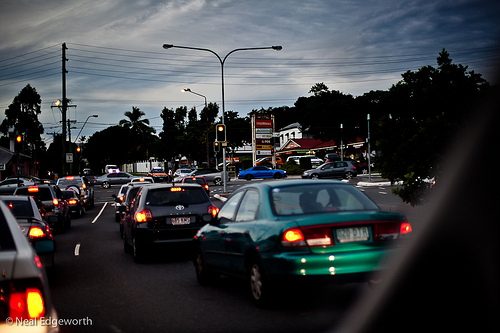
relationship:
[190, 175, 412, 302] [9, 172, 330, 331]
car on street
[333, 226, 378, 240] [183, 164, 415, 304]
license plate on rear car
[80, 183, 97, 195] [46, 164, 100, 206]
tail light on car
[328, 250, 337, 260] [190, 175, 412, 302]
light reflecting on car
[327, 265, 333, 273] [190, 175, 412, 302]
light reflecting on car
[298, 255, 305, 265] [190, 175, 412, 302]
light reflecting on car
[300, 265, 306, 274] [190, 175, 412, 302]
light reflecting on car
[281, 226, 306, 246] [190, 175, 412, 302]
lights on car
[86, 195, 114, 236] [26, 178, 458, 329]
white line on middle of street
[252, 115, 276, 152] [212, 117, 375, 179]
signs for shopping center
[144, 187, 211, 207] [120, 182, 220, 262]
window of a car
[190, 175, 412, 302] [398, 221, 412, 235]
car moving lights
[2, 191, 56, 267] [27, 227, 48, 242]
car moving lights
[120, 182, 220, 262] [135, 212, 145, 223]
car advancing taillight